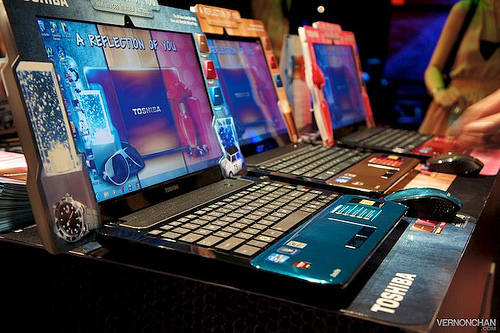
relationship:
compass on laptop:
[52, 196, 88, 244] [0, 1, 411, 300]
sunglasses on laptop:
[102, 139, 145, 186] [0, 1, 411, 300]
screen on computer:
[36, 16, 225, 199] [295, 17, 464, 159]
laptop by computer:
[0, 1, 411, 300] [295, 17, 464, 159]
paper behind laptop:
[1, 145, 34, 189] [0, 1, 411, 300]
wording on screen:
[74, 31, 178, 51] [36, 16, 225, 199]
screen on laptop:
[36, 16, 225, 199] [0, 1, 411, 300]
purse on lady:
[418, 0, 478, 133] [417, 0, 499, 135]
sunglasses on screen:
[102, 139, 145, 186] [36, 16, 225, 199]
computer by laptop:
[295, 17, 464, 159] [0, 1, 411, 300]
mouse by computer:
[382, 188, 463, 222] [295, 17, 464, 159]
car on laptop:
[219, 143, 248, 179] [0, 1, 411, 300]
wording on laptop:
[74, 31, 178, 51] [0, 1, 411, 300]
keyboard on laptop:
[148, 178, 338, 256] [0, 1, 411, 300]